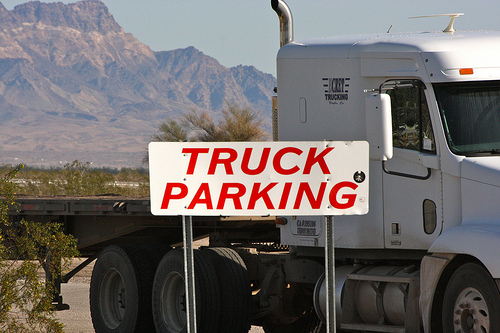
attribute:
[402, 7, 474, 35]
antenna — wifi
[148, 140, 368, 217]
sign — in picture, red and white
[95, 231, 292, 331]
wheels — semi truck, black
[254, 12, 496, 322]
cab — in picture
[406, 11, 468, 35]
antenna — in picture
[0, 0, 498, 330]
truck — in picture, white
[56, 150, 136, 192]
grass — green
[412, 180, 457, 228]
ground — in picture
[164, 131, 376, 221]
words — in picture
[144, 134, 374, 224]
words — red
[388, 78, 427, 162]
skateboard — in picture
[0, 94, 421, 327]
rest stop — in picture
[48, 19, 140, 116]
mountains — in picture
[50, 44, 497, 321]
truck — white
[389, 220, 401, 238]
handle — door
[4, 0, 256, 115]
mountain — grey